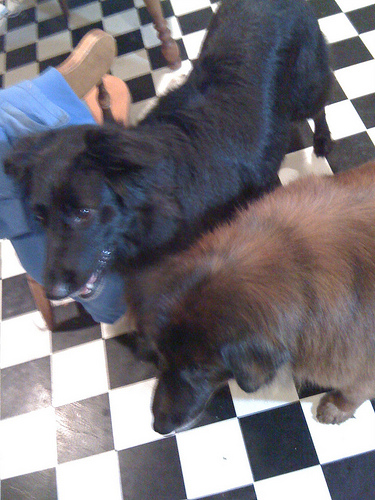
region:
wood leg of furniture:
[144, 0, 181, 70]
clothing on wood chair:
[1, 29, 131, 329]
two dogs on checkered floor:
[0, 1, 374, 437]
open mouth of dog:
[51, 252, 111, 301]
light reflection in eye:
[76, 208, 89, 218]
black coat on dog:
[6, 1, 334, 303]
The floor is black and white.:
[0, 366, 113, 498]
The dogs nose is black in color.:
[149, 411, 175, 435]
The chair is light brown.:
[66, 27, 120, 90]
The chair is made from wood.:
[73, 27, 123, 89]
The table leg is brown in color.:
[140, 0, 185, 70]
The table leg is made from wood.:
[141, 0, 183, 70]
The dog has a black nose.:
[42, 281, 69, 300]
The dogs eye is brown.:
[74, 208, 91, 218]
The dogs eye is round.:
[73, 202, 91, 220]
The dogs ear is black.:
[83, 126, 156, 171]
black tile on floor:
[322, 131, 372, 170]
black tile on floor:
[316, 448, 372, 498]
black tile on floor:
[235, 399, 320, 482]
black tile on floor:
[115, 436, 185, 498]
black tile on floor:
[1, 466, 58, 499]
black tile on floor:
[52, 390, 114, 465]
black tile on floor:
[172, 381, 237, 434]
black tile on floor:
[293, 376, 326, 398]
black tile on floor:
[1, 353, 52, 422]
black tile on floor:
[102, 328, 159, 390]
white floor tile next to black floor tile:
[48, 339, 108, 407]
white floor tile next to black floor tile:
[54, 450, 123, 498]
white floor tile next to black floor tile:
[108, 376, 176, 449]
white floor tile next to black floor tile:
[176, 416, 254, 498]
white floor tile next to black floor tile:
[227, 358, 298, 417]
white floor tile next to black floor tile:
[300, 391, 374, 465]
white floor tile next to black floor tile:
[253, 462, 331, 497]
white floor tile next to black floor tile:
[276, 173, 335, 186]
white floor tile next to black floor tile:
[0, 237, 28, 281]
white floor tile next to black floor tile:
[2, 309, 51, 367]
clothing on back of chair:
[1, 30, 130, 327]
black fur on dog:
[6, 0, 332, 305]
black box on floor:
[238, 398, 319, 479]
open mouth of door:
[47, 252, 110, 302]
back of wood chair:
[58, 29, 118, 125]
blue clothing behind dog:
[0, 67, 125, 323]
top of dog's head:
[131, 253, 286, 433]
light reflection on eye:
[76, 207, 89, 217]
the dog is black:
[4, 36, 173, 316]